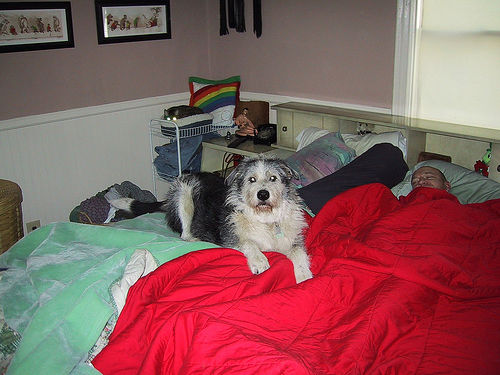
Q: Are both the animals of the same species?
A: No, they are dogs and cats.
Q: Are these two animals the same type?
A: No, they are dogs and cats.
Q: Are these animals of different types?
A: Yes, they are dogs and cats.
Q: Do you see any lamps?
A: No, there are no lamps.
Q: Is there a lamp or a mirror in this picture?
A: No, there are no lamps or mirrors.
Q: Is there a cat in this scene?
A: Yes, there is a cat.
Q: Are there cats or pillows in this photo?
A: Yes, there is a cat.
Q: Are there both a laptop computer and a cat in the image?
A: No, there is a cat but no laptops.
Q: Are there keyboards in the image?
A: No, there are no keyboards.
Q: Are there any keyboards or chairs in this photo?
A: No, there are no keyboards or chairs.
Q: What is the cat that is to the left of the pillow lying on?
A: The cat is lying on the basket.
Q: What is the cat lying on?
A: The cat is lying on the basket.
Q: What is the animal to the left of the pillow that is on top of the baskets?
A: The animal is a cat.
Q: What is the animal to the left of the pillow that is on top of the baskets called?
A: The animal is a cat.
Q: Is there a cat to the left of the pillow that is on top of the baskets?
A: Yes, there is a cat to the left of the pillow.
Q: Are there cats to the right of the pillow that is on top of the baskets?
A: No, the cat is to the left of the pillow.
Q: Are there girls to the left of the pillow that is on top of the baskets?
A: No, there is a cat to the left of the pillow.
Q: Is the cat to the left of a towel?
A: No, the cat is to the left of the pillow.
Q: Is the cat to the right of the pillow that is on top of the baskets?
A: No, the cat is to the left of the pillow.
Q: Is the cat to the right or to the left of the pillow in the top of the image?
A: The cat is to the left of the pillow.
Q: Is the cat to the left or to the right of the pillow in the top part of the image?
A: The cat is to the left of the pillow.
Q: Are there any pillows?
A: Yes, there are pillows.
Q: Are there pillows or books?
A: Yes, there are pillows.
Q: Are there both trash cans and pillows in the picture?
A: No, there are pillows but no trash cans.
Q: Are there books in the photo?
A: No, there are no books.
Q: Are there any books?
A: No, there are no books.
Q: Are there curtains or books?
A: No, there are no books or curtains.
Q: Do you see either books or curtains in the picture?
A: No, there are no books or curtains.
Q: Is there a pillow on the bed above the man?
A: Yes, there are pillows on the bed.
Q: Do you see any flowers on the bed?
A: No, there are pillows on the bed.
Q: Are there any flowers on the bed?
A: No, there are pillows on the bed.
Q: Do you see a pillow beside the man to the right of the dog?
A: Yes, there are pillows beside the man.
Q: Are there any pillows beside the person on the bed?
A: Yes, there are pillows beside the man.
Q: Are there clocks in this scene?
A: No, there are no clocks.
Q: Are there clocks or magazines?
A: No, there are no clocks or magazines.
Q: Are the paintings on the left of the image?
A: Yes, the paintings are on the left of the image.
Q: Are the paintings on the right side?
A: No, the paintings are on the left of the image.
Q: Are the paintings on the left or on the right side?
A: The paintings are on the left of the image.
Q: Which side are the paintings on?
A: The paintings are on the left of the image.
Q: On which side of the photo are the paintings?
A: The paintings are on the left of the image.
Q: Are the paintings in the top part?
A: Yes, the paintings are in the top of the image.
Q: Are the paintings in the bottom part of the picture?
A: No, the paintings are in the top of the image.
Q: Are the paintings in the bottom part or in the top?
A: The paintings are in the top of the image.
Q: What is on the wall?
A: The paintings are on the wall.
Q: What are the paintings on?
A: The paintings are on the wall.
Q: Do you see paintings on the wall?
A: Yes, there are paintings on the wall.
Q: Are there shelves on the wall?
A: No, there are paintings on the wall.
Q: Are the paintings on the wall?
A: Yes, the paintings are on the wall.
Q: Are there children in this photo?
A: No, there are no children.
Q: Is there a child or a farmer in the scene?
A: No, there are no children or farmers.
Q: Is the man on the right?
A: Yes, the man is on the right of the image.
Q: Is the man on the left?
A: No, the man is on the right of the image.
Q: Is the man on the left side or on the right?
A: The man is on the right of the image.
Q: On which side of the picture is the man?
A: The man is on the right of the image.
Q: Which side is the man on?
A: The man is on the right of the image.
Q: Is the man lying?
A: Yes, the man is lying.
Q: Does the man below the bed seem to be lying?
A: Yes, the man is lying.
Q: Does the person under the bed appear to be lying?
A: Yes, the man is lying.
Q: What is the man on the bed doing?
A: The man is lying.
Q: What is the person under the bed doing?
A: The man is lying.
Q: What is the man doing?
A: The man is lying.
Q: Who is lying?
A: The man is lying.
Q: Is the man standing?
A: No, the man is lying.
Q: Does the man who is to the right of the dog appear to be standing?
A: No, the man is lying.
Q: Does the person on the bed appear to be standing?
A: No, the man is lying.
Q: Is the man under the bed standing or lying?
A: The man is lying.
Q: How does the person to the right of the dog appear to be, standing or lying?
A: The man is lying.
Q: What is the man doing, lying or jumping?
A: The man is lying.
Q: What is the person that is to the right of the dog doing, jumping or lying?
A: The man is lying.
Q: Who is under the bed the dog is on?
A: The man is under the bed.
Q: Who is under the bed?
A: The man is under the bed.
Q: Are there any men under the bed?
A: Yes, there is a man under the bed.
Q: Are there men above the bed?
A: No, the man is under the bed.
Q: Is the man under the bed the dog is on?
A: Yes, the man is under the bed.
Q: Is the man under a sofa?
A: No, the man is under the bed.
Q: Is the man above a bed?
A: No, the man is under a bed.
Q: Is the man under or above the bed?
A: The man is under the bed.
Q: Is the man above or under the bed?
A: The man is under the bed.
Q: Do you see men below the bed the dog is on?
A: Yes, there is a man below the bed.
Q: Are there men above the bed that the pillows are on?
A: No, the man is below the bed.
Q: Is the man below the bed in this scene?
A: Yes, the man is below the bed.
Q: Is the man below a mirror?
A: No, the man is below the bed.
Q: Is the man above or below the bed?
A: The man is below the bed.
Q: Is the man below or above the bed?
A: The man is below the bed.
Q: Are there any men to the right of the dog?
A: Yes, there is a man to the right of the dog.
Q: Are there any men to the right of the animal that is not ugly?
A: Yes, there is a man to the right of the dog.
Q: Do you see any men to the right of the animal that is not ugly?
A: Yes, there is a man to the right of the dog.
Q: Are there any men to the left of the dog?
A: No, the man is to the right of the dog.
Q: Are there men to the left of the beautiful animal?
A: No, the man is to the right of the dog.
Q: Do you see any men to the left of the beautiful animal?
A: No, the man is to the right of the dog.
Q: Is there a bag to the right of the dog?
A: No, there is a man to the right of the dog.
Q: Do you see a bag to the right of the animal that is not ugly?
A: No, there is a man to the right of the dog.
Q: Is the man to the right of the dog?
A: Yes, the man is to the right of the dog.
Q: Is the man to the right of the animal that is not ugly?
A: Yes, the man is to the right of the dog.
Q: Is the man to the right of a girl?
A: No, the man is to the right of the dog.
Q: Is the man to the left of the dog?
A: No, the man is to the right of the dog.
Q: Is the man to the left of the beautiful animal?
A: No, the man is to the right of the dog.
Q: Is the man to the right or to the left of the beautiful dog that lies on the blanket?
A: The man is to the right of the dog.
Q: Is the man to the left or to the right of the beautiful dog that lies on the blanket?
A: The man is to the right of the dog.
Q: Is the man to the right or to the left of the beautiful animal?
A: The man is to the right of the dog.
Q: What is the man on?
A: The man is on the bed.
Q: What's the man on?
A: The man is on the bed.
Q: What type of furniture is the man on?
A: The man is on the bed.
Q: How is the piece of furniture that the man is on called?
A: The piece of furniture is a bed.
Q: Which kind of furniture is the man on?
A: The man is on the bed.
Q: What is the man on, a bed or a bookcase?
A: The man is on a bed.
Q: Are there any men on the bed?
A: Yes, there is a man on the bed.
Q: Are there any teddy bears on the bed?
A: No, there is a man on the bed.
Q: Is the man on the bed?
A: Yes, the man is on the bed.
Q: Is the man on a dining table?
A: No, the man is on the bed.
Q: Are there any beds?
A: Yes, there is a bed.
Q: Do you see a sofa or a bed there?
A: Yes, there is a bed.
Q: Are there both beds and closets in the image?
A: No, there is a bed but no closets.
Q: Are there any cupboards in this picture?
A: No, there are no cupboards.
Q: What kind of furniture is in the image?
A: The furniture is a bed.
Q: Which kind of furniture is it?
A: The piece of furniture is a bed.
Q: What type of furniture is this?
A: This is a bed.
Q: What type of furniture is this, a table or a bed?
A: This is a bed.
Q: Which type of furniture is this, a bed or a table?
A: This is a bed.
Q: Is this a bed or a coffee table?
A: This is a bed.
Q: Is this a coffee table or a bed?
A: This is a bed.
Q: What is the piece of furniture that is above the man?
A: The piece of furniture is a bed.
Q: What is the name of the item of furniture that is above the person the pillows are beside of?
A: The piece of furniture is a bed.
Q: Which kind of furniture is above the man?
A: The piece of furniture is a bed.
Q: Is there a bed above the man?
A: Yes, there is a bed above the man.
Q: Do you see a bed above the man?
A: Yes, there is a bed above the man.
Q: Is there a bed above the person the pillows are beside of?
A: Yes, there is a bed above the man.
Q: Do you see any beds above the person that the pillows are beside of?
A: Yes, there is a bed above the man.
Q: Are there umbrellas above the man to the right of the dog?
A: No, there is a bed above the man.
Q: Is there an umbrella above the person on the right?
A: No, there is a bed above the man.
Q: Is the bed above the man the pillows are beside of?
A: Yes, the bed is above the man.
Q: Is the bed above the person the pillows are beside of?
A: Yes, the bed is above the man.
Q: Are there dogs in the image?
A: Yes, there is a dog.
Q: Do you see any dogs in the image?
A: Yes, there is a dog.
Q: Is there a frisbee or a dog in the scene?
A: Yes, there is a dog.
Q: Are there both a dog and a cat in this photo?
A: Yes, there are both a dog and a cat.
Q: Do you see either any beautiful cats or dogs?
A: Yes, there is a beautiful dog.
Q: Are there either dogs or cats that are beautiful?
A: Yes, the dog is beautiful.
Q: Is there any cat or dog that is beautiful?
A: Yes, the dog is beautiful.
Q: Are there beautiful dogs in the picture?
A: Yes, there is a beautiful dog.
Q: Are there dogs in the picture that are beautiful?
A: Yes, there is a dog that is beautiful.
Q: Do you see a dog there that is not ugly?
A: Yes, there is an beautiful dog.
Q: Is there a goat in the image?
A: No, there are no goats.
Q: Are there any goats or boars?
A: No, there are no goats or boars.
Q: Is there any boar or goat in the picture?
A: No, there are no goats or boars.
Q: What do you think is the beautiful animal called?
A: The animal is a dog.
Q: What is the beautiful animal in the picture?
A: The animal is a dog.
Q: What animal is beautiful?
A: The animal is a dog.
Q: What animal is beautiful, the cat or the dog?
A: The dog is beautiful.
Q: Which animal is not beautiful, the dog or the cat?
A: The cat is not beautiful.